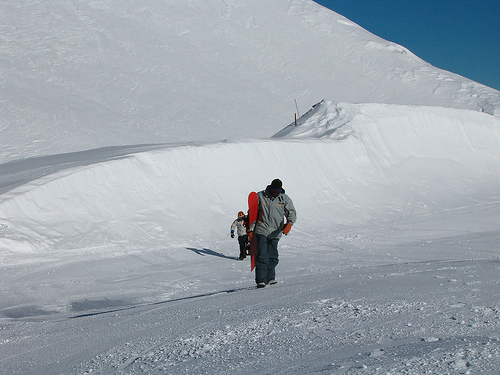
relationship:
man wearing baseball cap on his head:
[249, 178, 296, 287] [269, 179, 284, 194]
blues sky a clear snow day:
[320, 1, 498, 91] [0, 0, 498, 374]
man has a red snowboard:
[249, 178, 296, 287] [244, 192, 259, 271]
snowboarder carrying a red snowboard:
[257, 179, 296, 287] [244, 192, 259, 271]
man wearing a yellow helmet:
[230, 211, 247, 262] [236, 211, 246, 219]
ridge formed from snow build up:
[1, 99, 499, 181] [301, 97, 497, 260]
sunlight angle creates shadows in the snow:
[0, 0, 498, 374] [0, 142, 185, 195]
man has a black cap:
[249, 178, 296, 287] [269, 179, 284, 194]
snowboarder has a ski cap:
[230, 211, 247, 262] [236, 211, 246, 219]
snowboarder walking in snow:
[249, 178, 296, 287] [1, 1, 231, 375]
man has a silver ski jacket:
[249, 178, 296, 287] [256, 190, 296, 239]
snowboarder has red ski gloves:
[257, 179, 296, 287] [282, 222, 291, 234]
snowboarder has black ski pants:
[230, 211, 247, 262] [236, 234, 248, 257]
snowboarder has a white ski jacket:
[230, 211, 247, 262] [231, 220, 247, 237]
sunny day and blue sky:
[0, 0, 498, 374] [320, 1, 498, 91]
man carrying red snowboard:
[249, 178, 296, 287] [244, 190, 258, 272]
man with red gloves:
[249, 178, 296, 287] [282, 222, 291, 234]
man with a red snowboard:
[257, 179, 296, 287] [244, 192, 259, 271]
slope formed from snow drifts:
[0, 100, 277, 202] [301, 97, 497, 260]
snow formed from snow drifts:
[1, 2, 498, 178] [1, 99, 499, 181]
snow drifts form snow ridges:
[1, 99, 499, 181] [273, 88, 499, 148]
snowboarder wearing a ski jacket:
[257, 179, 296, 287] [256, 190, 296, 239]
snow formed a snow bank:
[1, 2, 498, 178] [273, 88, 499, 148]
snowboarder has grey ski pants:
[257, 179, 296, 287] [252, 232, 278, 285]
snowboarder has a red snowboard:
[257, 179, 296, 287] [244, 192, 259, 271]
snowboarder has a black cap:
[257, 179, 296, 287] [269, 179, 284, 194]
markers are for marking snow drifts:
[289, 96, 301, 126] [273, 88, 499, 148]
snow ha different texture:
[1, 2, 498, 178] [0, 0, 498, 374]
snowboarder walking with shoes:
[257, 179, 296, 287] [255, 282, 265, 289]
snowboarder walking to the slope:
[257, 179, 296, 287] [1, 288, 499, 375]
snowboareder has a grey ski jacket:
[249, 178, 296, 287] [256, 190, 296, 239]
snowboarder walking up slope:
[230, 211, 247, 262] [1, 288, 499, 375]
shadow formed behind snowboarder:
[185, 247, 239, 263] [230, 211, 247, 262]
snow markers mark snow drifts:
[292, 96, 300, 121] [273, 88, 499, 148]